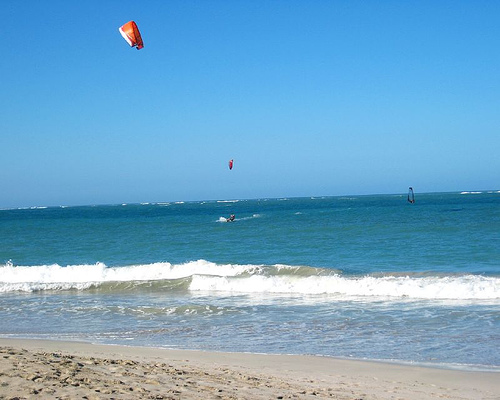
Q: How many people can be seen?
A: One.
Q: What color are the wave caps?
A: White.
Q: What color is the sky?
A: Blue.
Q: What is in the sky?
A: Kites.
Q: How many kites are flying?
A: Two.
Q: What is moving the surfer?
A: Wind in the kite.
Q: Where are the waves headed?
A: Shore.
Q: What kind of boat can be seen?
A: Sailboat.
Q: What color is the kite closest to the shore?
A: Orange, white, and black.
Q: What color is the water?
A: Blue.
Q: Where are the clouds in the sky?
A: Nowhere.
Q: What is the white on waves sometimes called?
A: Froth.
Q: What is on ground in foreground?
A: Sand.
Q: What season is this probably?
A: Summer.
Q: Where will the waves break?
A: On shore.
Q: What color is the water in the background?
A: Deep turquoise blue.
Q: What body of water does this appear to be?
A: Ocean.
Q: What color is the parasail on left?
A: Orange with white.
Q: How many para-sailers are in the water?
A: One.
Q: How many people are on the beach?
A: None.